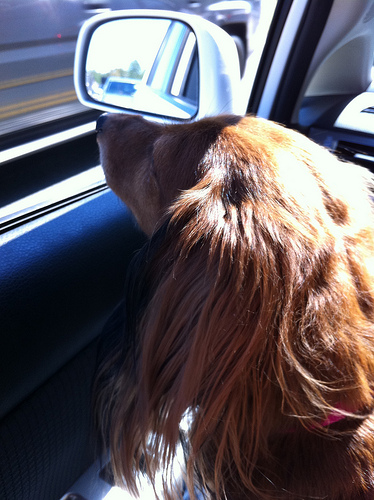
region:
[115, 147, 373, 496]
th edog is in the car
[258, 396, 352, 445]
the colar is pink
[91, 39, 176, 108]
reflection is in the mirror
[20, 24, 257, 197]
the window is open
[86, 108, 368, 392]
the dog is looking outside the window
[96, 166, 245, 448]
the hair is brown and black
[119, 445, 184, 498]
light refelction is on the door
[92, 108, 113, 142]
the nose is black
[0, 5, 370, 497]
it is daytime in the picture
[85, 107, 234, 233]
the dog is looking outside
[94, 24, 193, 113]
the mirror is concave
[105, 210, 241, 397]
the dog is brown and black in color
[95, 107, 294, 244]
the dog is looking through the window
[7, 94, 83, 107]
the road is apinted yellow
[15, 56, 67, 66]
the road is tarmac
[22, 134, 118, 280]
the door is closed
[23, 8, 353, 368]
the scene is inside the car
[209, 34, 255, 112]
the car is whirte in color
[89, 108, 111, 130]
the nose of the dog is black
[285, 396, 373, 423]
the colar is pink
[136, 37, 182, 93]
part of a mirror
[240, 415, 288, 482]
hair of a dog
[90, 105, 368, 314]
A dog having fun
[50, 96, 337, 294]
A dog looking out the window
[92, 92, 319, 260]
A dog going for a joyride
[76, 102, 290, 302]
A brown dog staring outside the car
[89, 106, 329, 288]
A brown dog entertaining himself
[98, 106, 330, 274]
A dog loving the ride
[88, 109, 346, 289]
A brown dog enjoying his car ride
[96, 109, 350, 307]
A brown dog staring at traffic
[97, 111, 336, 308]
A brown dog having the time of their life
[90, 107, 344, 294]
A brown dog enjoying a nice car ride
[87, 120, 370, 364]
A brown hairy dog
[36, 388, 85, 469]
A grey car seat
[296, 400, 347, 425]
A pink robbin on the god's neck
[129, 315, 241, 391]
A hairly ear of a dog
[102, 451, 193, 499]
Strong and shiny sunrays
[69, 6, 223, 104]
A car side mirror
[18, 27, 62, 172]
A clear car window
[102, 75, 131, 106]
A car at the back reflection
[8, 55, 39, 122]
Yellow pole outside the car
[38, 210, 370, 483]
A car from inside